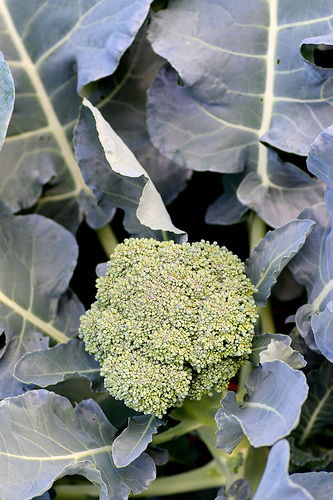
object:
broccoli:
[0, 3, 331, 499]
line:
[226, 379, 242, 394]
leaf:
[67, 96, 188, 244]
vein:
[96, 185, 143, 212]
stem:
[178, 382, 235, 479]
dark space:
[112, 209, 126, 242]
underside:
[86, 102, 187, 242]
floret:
[78, 233, 258, 418]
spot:
[273, 56, 282, 67]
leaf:
[147, 3, 331, 234]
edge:
[69, 96, 88, 136]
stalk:
[153, 420, 198, 449]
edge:
[171, 426, 198, 438]